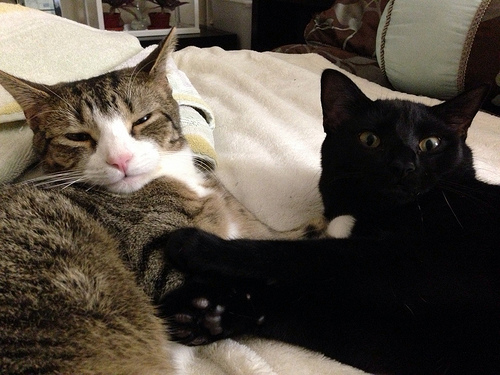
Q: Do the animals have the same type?
A: Yes, all the animals are cats.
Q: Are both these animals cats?
A: Yes, all the animals are cats.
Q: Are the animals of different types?
A: No, all the animals are cats.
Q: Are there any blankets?
A: Yes, there is a blanket.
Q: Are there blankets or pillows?
A: Yes, there is a blanket.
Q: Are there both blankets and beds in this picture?
A: Yes, there are both a blanket and a bed.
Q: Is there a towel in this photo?
A: No, there are no towels.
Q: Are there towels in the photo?
A: No, there are no towels.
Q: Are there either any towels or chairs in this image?
A: No, there are no towels or chairs.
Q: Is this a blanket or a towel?
A: This is a blanket.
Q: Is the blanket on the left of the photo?
A: Yes, the blanket is on the left of the image.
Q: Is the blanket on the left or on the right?
A: The blanket is on the left of the image.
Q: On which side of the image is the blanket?
A: The blanket is on the left of the image.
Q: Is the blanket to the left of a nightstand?
A: No, the blanket is to the left of a cat.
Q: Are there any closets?
A: No, there are no closets.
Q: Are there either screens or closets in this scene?
A: No, there are no closets or screens.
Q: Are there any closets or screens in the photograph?
A: No, there are no closets or screens.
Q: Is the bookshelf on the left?
A: Yes, the bookshelf is on the left of the image.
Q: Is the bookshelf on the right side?
A: No, the bookshelf is on the left of the image.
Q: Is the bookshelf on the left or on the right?
A: The bookshelf is on the left of the image.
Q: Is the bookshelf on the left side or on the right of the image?
A: The bookshelf is on the left of the image.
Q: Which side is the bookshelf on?
A: The bookshelf is on the left of the image.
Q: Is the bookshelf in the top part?
A: Yes, the bookshelf is in the top of the image.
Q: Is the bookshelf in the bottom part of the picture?
A: No, the bookshelf is in the top of the image.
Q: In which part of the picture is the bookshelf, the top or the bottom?
A: The bookshelf is in the top of the image.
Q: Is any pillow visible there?
A: Yes, there is a pillow.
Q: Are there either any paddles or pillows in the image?
A: Yes, there is a pillow.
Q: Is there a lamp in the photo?
A: No, there are no lamps.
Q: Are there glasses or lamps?
A: No, there are no lamps or glasses.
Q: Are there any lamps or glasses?
A: No, there are no lamps or glasses.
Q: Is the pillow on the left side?
A: Yes, the pillow is on the left of the image.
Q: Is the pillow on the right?
A: No, the pillow is on the left of the image.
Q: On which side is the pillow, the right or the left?
A: The pillow is on the left of the image.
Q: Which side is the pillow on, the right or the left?
A: The pillow is on the left of the image.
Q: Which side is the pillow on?
A: The pillow is on the left of the image.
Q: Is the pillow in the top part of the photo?
A: Yes, the pillow is in the top of the image.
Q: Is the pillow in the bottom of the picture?
A: No, the pillow is in the top of the image.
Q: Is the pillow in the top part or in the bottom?
A: The pillow is in the top of the image.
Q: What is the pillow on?
A: The pillow is on the bed.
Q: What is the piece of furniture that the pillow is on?
A: The piece of furniture is a bed.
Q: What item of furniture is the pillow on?
A: The pillow is on the bed.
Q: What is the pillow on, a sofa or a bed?
A: The pillow is on a bed.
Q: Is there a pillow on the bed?
A: Yes, there is a pillow on the bed.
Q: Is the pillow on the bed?
A: Yes, the pillow is on the bed.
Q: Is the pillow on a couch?
A: No, the pillow is on the bed.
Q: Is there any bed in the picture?
A: Yes, there is a bed.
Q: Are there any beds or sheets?
A: Yes, there is a bed.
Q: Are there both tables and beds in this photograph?
A: No, there is a bed but no tables.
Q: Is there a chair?
A: No, there are no chairs.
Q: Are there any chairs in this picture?
A: No, there are no chairs.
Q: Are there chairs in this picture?
A: No, there are no chairs.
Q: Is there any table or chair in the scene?
A: No, there are no chairs or tables.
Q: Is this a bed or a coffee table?
A: This is a bed.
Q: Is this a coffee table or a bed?
A: This is a bed.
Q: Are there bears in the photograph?
A: No, there are no bears.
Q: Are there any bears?
A: No, there are no bears.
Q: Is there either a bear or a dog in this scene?
A: No, there are no bears or dogs.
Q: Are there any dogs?
A: No, there are no dogs.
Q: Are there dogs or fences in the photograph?
A: No, there are no dogs or fences.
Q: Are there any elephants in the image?
A: No, there are no elephants.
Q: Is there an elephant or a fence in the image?
A: No, there are no elephants or fences.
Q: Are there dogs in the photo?
A: No, there are no dogs.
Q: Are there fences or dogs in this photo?
A: No, there are no dogs or fences.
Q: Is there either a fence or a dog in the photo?
A: No, there are no dogs or fences.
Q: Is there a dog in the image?
A: No, there are no dogs.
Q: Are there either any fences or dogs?
A: No, there are no dogs or fences.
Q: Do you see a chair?
A: No, there are no chairs.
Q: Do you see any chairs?
A: No, there are no chairs.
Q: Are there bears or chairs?
A: No, there are no chairs or bears.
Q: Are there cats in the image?
A: Yes, there is a cat.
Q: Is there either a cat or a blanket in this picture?
A: Yes, there is a cat.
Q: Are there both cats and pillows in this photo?
A: Yes, there are both a cat and a pillow.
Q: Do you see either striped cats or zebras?
A: Yes, there is a striped cat.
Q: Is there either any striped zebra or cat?
A: Yes, there is a striped cat.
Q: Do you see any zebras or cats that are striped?
A: Yes, the cat is striped.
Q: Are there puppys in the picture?
A: No, there are no puppys.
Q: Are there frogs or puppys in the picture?
A: No, there are no puppys or frogs.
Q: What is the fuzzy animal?
A: The animal is a cat.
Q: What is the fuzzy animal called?
A: The animal is a cat.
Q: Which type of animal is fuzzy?
A: The animal is a cat.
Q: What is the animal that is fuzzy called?
A: The animal is a cat.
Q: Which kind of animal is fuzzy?
A: The animal is a cat.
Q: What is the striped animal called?
A: The animal is a cat.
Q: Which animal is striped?
A: The animal is a cat.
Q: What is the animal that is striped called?
A: The animal is a cat.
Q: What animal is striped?
A: The animal is a cat.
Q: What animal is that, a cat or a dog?
A: That is a cat.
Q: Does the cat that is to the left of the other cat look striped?
A: Yes, the cat is striped.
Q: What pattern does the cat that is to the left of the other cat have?
A: The cat has striped pattern.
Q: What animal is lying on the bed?
A: The animal is a cat.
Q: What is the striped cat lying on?
A: The cat is lying on the bed.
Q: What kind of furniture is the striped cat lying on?
A: The cat is lying on the bed.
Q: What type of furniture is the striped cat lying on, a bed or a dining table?
A: The cat is lying on a bed.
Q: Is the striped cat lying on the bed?
A: Yes, the cat is lying on the bed.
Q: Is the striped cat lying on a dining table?
A: No, the cat is lying on the bed.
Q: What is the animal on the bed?
A: The animal is a cat.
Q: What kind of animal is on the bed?
A: The animal is a cat.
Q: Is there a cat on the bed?
A: Yes, there is a cat on the bed.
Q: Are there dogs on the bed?
A: No, there is a cat on the bed.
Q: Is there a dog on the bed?
A: No, there is a cat on the bed.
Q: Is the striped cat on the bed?
A: Yes, the cat is on the bed.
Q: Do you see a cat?
A: Yes, there is a cat.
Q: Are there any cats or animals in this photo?
A: Yes, there is a cat.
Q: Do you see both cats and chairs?
A: No, there is a cat but no chairs.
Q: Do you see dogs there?
A: No, there are no dogs.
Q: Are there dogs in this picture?
A: No, there are no dogs.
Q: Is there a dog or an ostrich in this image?
A: No, there are no dogs or ostriches.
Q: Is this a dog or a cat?
A: This is a cat.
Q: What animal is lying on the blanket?
A: The cat is lying on the blanket.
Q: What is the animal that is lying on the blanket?
A: The animal is a cat.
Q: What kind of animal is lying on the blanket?
A: The animal is a cat.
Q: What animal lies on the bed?
A: The cat lies on the bed.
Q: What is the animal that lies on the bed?
A: The animal is a cat.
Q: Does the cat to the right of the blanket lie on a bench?
A: No, the cat lies on a bed.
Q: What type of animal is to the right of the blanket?
A: The animal is a cat.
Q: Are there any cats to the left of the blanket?
A: No, the cat is to the right of the blanket.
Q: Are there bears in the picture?
A: No, there are no bears.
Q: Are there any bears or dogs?
A: No, there are no bears or dogs.